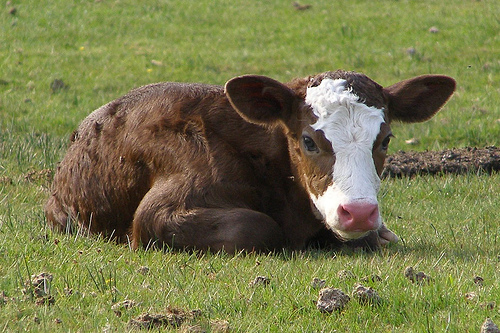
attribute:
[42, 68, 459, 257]
baby cow —  baby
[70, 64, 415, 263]
cow — brown, white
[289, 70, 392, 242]
face — white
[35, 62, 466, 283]
cow — brown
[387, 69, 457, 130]
ear — big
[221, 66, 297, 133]
ear — big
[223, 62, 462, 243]
head — white, brown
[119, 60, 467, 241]
cow — baby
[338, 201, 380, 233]
nose — pink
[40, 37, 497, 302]
cow — baby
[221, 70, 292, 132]
ear — big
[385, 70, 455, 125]
ear — big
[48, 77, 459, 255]
cow — brown, baby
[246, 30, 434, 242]
face — white